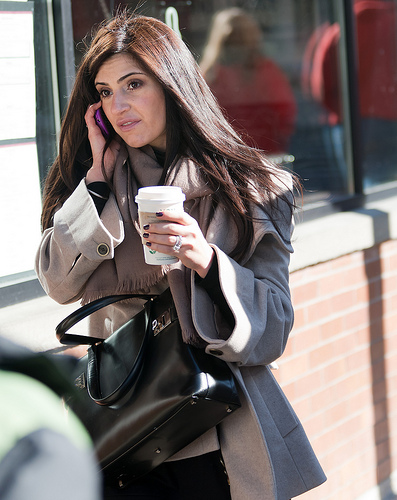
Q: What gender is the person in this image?
A: Female.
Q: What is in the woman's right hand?
A: A phone.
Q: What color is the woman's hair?
A: Brown.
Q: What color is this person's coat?
A: Tan.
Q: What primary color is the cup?
A: White.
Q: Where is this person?
A: A city street.